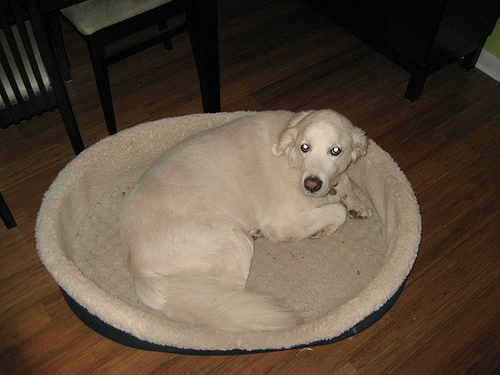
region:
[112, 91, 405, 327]
a white dog in a bed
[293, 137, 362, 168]
bright eyes of the dog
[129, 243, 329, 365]
white fluffy dog tail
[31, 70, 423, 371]
a dog laying in its bed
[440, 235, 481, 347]
brown hardwood floor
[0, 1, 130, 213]
a wooden chair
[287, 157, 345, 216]
dog's snout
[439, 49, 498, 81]
white trim on the wall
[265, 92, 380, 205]
a dogs head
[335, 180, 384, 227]
white dog paw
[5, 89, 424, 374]
dog lying in his bed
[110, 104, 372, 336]
dog with white hair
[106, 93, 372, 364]
dog with brown nose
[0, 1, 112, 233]
a wooden dining chair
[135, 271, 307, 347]
fluffy tail of a dog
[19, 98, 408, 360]
a medium sized dog bed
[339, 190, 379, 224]
paw on a dog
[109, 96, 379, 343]
dog looking at the camera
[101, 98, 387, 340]
dog with shining eyes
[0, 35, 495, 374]
floor is made of laminate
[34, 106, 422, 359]
white dog laying in dog bed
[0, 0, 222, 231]
two black chairs with cushions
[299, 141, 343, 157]
dogs eyes are open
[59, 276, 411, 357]
outside of bed is black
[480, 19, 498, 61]
patch of green wall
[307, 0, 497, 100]
corner of a wooden piece of furniture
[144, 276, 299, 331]
a white fluffy dogs tail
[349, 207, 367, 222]
dark pads of dogs paw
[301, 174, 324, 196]
pinks nose surrounded by black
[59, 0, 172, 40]
white cushion on chair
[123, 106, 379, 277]
Dog in a bed.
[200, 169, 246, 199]
The dog is white.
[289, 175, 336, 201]
The nose is brown.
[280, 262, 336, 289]
Inside of the bed is beige.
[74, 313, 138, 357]
The outside of the bed is black.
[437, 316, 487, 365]
The floor is wooden.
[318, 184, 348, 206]
Tag on the collar.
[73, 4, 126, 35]
Cushion on the chair.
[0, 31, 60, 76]
Bars on the chair.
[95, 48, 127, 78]
The chair is black.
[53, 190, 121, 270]
Inside of the bed is beige.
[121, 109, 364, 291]
The dog is white.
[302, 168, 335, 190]
The nose is brown.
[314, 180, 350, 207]
Tag on the collar.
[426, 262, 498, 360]
The floor is hardwood.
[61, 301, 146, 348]
The outside of the bed is black.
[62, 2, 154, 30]
Cushion on the chair.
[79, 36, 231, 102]
The chair is black.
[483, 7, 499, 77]
The wall is green.